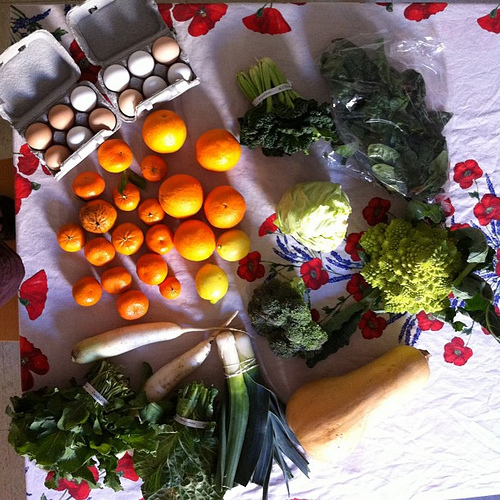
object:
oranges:
[53, 110, 250, 321]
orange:
[195, 127, 244, 172]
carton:
[0, 0, 202, 180]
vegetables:
[217, 28, 499, 499]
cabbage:
[273, 177, 354, 255]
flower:
[17, 268, 50, 323]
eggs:
[24, 35, 194, 171]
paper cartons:
[0, 0, 170, 127]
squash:
[357, 206, 471, 319]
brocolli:
[244, 268, 329, 359]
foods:
[5, 4, 499, 499]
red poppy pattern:
[158, 0, 499, 51]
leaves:
[314, 37, 455, 224]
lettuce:
[5, 358, 229, 496]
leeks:
[215, 327, 312, 500]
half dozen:
[98, 34, 197, 117]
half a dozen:
[19, 83, 123, 185]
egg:
[151, 35, 181, 65]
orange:
[159, 173, 206, 219]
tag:
[83, 381, 111, 409]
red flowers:
[242, 6, 292, 37]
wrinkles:
[450, 30, 497, 160]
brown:
[23, 100, 71, 168]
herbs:
[234, 54, 336, 160]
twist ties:
[250, 82, 293, 106]